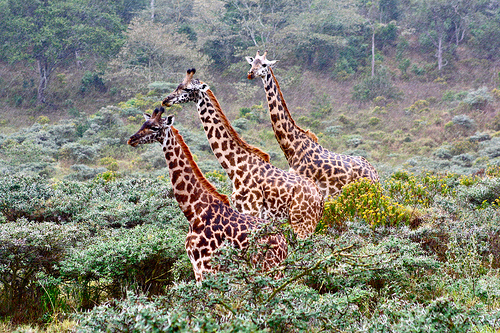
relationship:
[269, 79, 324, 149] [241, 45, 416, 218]
mane of giraffe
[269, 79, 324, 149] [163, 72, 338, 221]
mane of giraffe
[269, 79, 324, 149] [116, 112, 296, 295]
mane of giraffe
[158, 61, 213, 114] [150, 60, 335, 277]
head of giraffe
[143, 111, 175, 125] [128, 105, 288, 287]
ears of giraffe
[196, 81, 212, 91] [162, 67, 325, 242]
ears of giraffe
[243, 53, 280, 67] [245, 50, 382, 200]
ears of giraffe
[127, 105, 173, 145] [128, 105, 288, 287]
head of giraffe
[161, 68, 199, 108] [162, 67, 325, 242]
head of giraffe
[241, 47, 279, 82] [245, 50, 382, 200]
head of giraffe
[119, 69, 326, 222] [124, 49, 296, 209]
giraffe has neck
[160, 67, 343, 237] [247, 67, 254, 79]
giraffe has nose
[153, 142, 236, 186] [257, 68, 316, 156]
hair down giraffes neck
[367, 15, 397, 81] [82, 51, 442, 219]
tree in distance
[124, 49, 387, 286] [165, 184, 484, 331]
giraffes in bushes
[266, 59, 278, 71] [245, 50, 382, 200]
ear of a giraffe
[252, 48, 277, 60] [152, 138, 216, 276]
horn on a giraffe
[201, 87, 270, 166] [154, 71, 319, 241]
mane on giraffe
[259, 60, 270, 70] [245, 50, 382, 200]
eye of giraffe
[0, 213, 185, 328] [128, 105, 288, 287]
plants with giraffe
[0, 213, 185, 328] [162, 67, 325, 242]
plants with giraffe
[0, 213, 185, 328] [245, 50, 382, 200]
plants with giraffe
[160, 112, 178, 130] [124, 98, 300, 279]
ear of giraffe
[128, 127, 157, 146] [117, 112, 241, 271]
mouth of giraffe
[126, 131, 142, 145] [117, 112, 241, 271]
nose of giraffe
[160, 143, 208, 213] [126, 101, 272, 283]
neck of giraffe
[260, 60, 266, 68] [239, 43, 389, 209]
eye of giraffe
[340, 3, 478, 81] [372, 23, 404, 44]
trees with branches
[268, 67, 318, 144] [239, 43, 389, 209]
mane of giraffe